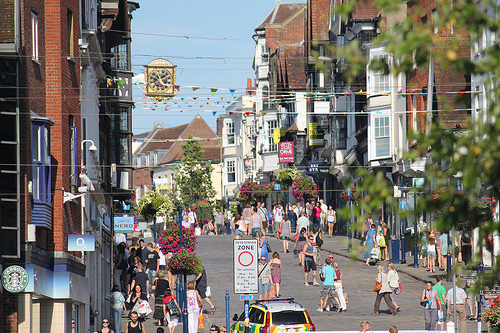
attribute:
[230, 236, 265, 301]
sign — white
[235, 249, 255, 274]
circle — red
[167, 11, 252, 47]
sky — blue, clear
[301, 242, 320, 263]
tanktop — gray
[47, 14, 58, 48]
bricks — red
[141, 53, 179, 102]
clock — gold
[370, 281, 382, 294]
purse — brown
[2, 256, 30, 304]
sign — round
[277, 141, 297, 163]
banner — red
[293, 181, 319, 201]
flowers — pink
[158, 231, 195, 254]
flowers — pink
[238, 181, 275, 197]
flowers — pink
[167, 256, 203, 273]
flowers — pink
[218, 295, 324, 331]
car — parked, multi-colored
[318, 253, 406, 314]
people — walking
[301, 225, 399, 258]
sidewalk — crowded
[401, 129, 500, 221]
branches — green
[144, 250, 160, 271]
shirt — black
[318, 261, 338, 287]
shirt — aqua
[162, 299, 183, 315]
bag — black